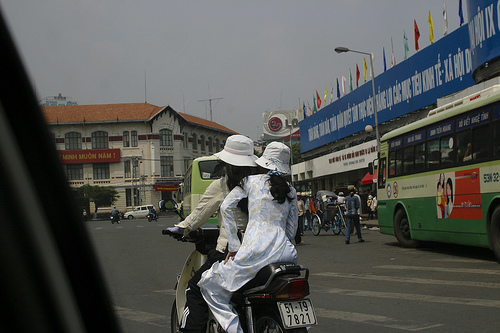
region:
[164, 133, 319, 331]
Two women riding on a motor vehicle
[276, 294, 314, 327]
A vehicles license plate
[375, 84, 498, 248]
A large bus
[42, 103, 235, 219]
A large building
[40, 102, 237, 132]
A large red roof of a building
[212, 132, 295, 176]
Two white hats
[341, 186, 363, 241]
A person standing in the street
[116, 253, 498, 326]
A street crosswalk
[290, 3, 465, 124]
A large collection of flags on buildings roof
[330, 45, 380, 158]
A large silver street light and pole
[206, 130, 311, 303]
the girls are riding a scooter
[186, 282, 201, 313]
the pants are black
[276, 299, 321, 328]
the tag is white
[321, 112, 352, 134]
the sign is blue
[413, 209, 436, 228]
the bus is green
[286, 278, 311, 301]
the tail len is red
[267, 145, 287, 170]
the hat is white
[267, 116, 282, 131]
the sign is red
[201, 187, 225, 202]
the jacket is tan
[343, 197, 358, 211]
the jacket is blue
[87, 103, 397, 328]
woman riding a motorcycle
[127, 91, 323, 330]
two women riding a motorcycle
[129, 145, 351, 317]
a motorcycle on the road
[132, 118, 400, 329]
a motorcycles on the street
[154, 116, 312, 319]
two people wearing hats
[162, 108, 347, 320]
two people wearing white hats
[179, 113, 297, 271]
people wearing hats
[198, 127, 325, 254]
people wearing white hats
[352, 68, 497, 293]
a bus on the road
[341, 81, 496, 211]
a bus on the street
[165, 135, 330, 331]
women riding on bike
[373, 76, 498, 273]
bus that carries passengers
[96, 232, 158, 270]
street area for vehicles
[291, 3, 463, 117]
flags on top of building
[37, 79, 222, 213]
building on corner of street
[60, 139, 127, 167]
plaque on side of building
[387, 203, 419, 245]
front tire on bus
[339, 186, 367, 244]
person walking across street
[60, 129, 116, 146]
windows on the building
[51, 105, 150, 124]
roof of the building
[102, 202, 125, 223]
A man riding on a motorcycle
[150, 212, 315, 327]
A red/white scooter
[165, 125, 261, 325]
A woman wearing a white hat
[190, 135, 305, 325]
A woman wearing a white hat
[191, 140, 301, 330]
A woman wearing a blue/white/yellow dress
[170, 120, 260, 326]
A woman wearing a white shirt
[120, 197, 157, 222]
A white car in the background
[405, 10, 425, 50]
A rolled up red flag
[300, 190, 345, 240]
A blue bike on the street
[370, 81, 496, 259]
A green/white bus